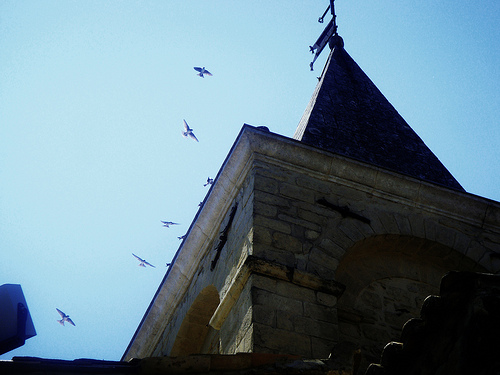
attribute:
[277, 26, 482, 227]
roof — tall, pointed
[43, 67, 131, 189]
sky — blue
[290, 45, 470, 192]
steeple — triangular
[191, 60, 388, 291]
building — tall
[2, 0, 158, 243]
sky — blue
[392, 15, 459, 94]
clouds — white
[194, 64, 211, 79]
bird — black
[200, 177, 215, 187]
bird — black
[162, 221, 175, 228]
bird — black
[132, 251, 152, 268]
bird — black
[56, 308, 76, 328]
bird — black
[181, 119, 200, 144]
bird — black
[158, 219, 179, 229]
bird — black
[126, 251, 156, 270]
bird — black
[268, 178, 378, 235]
brace — metal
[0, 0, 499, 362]
sky — blue